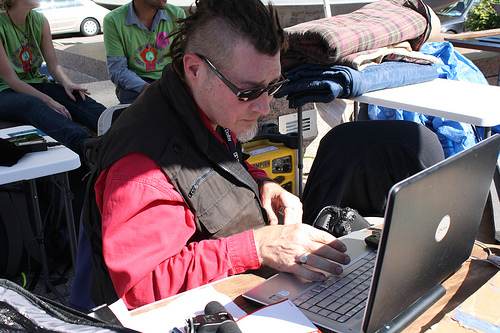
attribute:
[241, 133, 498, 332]
laptop — silver, black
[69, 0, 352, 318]
man — white, sitting, typing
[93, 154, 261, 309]
shirt — shiny, red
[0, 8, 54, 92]
tank-top — green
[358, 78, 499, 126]
table — white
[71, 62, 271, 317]
vest — black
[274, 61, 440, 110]
blanket — folded, blue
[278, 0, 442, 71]
blanket — folded, plaid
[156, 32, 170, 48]
sticker — pink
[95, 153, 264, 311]
sleeve — red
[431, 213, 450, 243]
emblem — white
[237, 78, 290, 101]
sunglasses — black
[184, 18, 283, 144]
head — partially-shaved